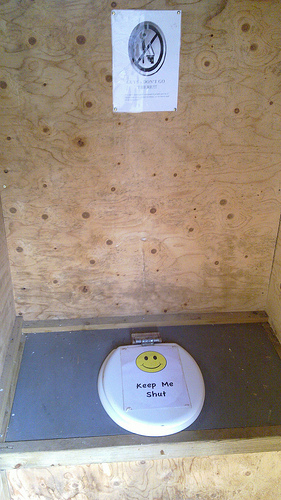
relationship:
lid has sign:
[103, 341, 203, 435] [120, 342, 191, 412]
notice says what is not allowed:
[115, 13, 178, 113] [126, 26, 165, 76]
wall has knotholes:
[75, 150, 244, 290] [64, 30, 113, 126]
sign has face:
[120, 342, 191, 412] [135, 349, 168, 374]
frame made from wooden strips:
[0, 306, 281, 452] [16, 313, 279, 335]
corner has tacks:
[246, 305, 274, 333] [253, 306, 274, 320]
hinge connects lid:
[129, 331, 165, 349] [97, 341, 206, 440]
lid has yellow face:
[103, 341, 203, 435] [139, 349, 164, 375]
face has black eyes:
[139, 349, 164, 375] [141, 351, 162, 363]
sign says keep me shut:
[127, 339, 191, 411] [134, 378, 179, 405]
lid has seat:
[97, 341, 206, 440] [5, 324, 279, 446]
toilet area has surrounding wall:
[5, 324, 279, 446] [0, 3, 281, 319]